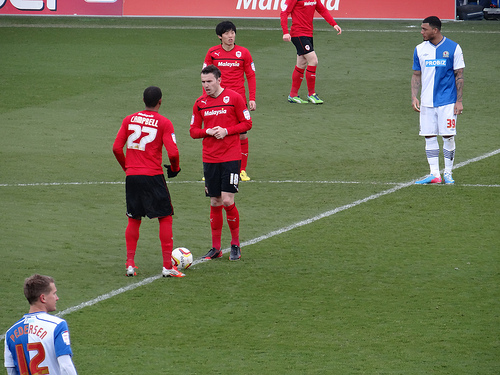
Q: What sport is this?
A: Soccer.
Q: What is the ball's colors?
A: White and red.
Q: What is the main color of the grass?
A: Green.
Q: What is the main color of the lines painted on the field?
A: White.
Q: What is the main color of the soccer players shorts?
A: Black.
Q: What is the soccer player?
A: Asian.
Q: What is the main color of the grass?
A: Green.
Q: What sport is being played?
A: Soccer.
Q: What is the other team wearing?
A: Blue and white.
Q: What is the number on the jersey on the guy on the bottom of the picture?
A: 12.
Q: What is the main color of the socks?
A: Red.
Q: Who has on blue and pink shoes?
A: The with the number 39.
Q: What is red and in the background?
A: The signs.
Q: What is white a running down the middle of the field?
A: A line.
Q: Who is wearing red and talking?
A: Two soccer players.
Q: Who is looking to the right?
A: The soccer player in the blue and white uniform.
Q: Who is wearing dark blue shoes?
A: The man standing on the soccer field.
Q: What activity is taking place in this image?
A: People playing soccer.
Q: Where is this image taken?
A: Soccer field.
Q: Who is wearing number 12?
A: Pedersen.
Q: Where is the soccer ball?
A: At number 27, Campbell's feet.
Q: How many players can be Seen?
A: 6.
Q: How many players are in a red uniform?
A: 4.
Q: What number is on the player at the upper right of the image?
A: 39.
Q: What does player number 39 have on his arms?
A: Tattoos.